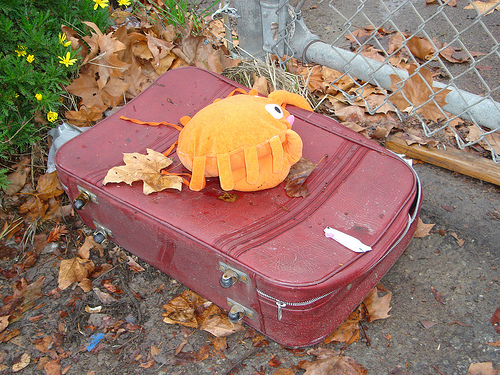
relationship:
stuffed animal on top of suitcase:
[155, 83, 314, 190] [51, 56, 434, 311]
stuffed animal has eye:
[155, 83, 314, 190] [266, 101, 293, 120]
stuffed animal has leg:
[155, 83, 314, 190] [190, 152, 209, 194]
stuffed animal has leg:
[155, 83, 314, 190] [214, 154, 243, 190]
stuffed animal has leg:
[155, 83, 314, 190] [269, 134, 289, 171]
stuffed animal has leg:
[155, 83, 314, 190] [270, 85, 307, 110]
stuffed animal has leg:
[155, 83, 314, 190] [178, 111, 192, 128]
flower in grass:
[89, 0, 111, 13] [2, 4, 134, 115]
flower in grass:
[116, 1, 134, 9] [2, 4, 134, 115]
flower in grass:
[12, 48, 26, 59] [2, 4, 134, 115]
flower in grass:
[26, 53, 45, 64] [2, 4, 134, 115]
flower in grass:
[59, 35, 71, 47] [2, 4, 134, 115]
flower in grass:
[56, 51, 82, 71] [2, 4, 134, 115]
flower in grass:
[32, 90, 51, 103] [2, 4, 134, 115]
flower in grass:
[43, 108, 68, 126] [2, 4, 134, 115]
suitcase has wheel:
[51, 56, 434, 311] [69, 196, 101, 208]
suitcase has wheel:
[51, 56, 434, 311] [93, 230, 108, 250]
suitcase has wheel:
[51, 56, 434, 311] [220, 270, 245, 289]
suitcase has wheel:
[51, 56, 434, 311] [225, 305, 250, 329]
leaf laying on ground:
[35, 173, 68, 197] [5, 173, 495, 357]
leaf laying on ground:
[50, 245, 95, 287] [5, 173, 495, 357]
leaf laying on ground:
[392, 76, 456, 120] [5, 173, 495, 357]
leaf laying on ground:
[365, 290, 400, 326] [5, 173, 495, 357]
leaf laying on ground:
[154, 291, 214, 335] [5, 173, 495, 357]